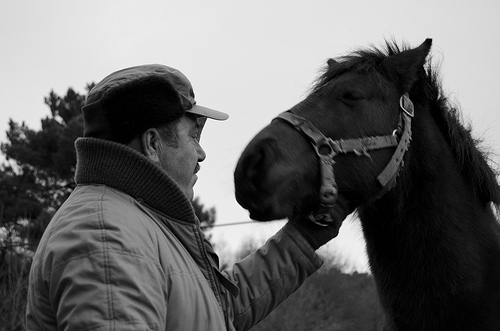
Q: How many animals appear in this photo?
A: One.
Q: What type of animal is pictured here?
A: Horse.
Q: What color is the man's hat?
A: Black.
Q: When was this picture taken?
A: Daytime.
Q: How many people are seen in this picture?
A: One.